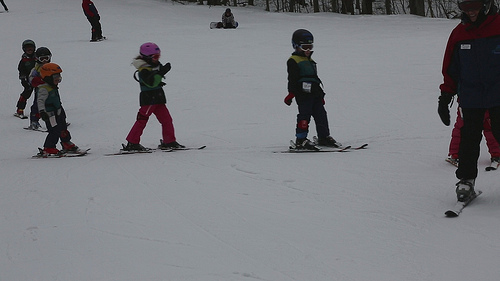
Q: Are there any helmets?
A: Yes, there is a helmet.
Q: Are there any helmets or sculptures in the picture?
A: Yes, there is a helmet.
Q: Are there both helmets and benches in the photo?
A: No, there is a helmet but no benches.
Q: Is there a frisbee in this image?
A: No, there are no frisbees.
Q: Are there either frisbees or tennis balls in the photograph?
A: No, there are no frisbees or tennis balls.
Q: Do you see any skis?
A: Yes, there are skis.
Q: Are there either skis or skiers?
A: Yes, there are skis.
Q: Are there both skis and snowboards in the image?
A: No, there are skis but no snowboards.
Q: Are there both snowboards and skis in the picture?
A: No, there are skis but no snowboards.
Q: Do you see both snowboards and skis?
A: No, there are skis but no snowboards.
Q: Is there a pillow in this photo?
A: No, there are no pillows.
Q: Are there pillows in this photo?
A: No, there are no pillows.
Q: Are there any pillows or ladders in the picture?
A: No, there are no pillows or ladders.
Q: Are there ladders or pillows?
A: No, there are no pillows or ladders.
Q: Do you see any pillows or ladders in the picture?
A: No, there are no pillows or ladders.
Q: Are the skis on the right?
A: Yes, the skis are on the right of the image.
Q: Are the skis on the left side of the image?
A: No, the skis are on the right of the image.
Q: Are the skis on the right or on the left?
A: The skis are on the right of the image.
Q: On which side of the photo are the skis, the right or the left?
A: The skis are on the right of the image.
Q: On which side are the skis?
A: The skis are on the right of the image.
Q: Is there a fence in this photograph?
A: No, there are no fences.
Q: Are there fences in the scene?
A: No, there are no fences.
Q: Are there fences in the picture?
A: No, there are no fences.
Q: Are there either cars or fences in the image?
A: No, there are no fences or cars.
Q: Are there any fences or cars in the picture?
A: No, there are no fences or cars.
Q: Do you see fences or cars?
A: No, there are no fences or cars.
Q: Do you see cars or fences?
A: No, there are no fences or cars.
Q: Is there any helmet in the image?
A: Yes, there is a helmet.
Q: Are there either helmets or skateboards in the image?
A: Yes, there is a helmet.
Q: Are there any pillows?
A: No, there are no pillows.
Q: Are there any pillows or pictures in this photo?
A: No, there are no pillows or pictures.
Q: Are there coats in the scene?
A: Yes, there is a coat.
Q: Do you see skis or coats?
A: Yes, there is a coat.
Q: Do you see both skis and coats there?
A: Yes, there are both a coat and skis.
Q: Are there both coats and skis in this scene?
A: Yes, there are both a coat and skis.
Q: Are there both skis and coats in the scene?
A: Yes, there are both a coat and skis.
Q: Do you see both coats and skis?
A: Yes, there are both a coat and skis.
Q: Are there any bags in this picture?
A: No, there are no bags.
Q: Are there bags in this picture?
A: No, there are no bags.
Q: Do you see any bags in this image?
A: No, there are no bags.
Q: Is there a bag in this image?
A: No, there are no bags.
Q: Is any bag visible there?
A: No, there are no bags.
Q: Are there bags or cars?
A: No, there are no bags or cars.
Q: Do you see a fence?
A: No, there are no fences.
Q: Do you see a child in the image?
A: Yes, there are children.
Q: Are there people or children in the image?
A: Yes, there are children.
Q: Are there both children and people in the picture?
A: Yes, there are both children and people.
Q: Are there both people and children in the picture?
A: Yes, there are both children and people.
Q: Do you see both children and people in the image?
A: Yes, there are both children and people.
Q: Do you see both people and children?
A: Yes, there are both children and people.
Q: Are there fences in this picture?
A: No, there are no fences.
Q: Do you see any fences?
A: No, there are no fences.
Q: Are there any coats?
A: Yes, there is a coat.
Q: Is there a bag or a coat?
A: Yes, there is a coat.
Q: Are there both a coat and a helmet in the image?
A: Yes, there are both a coat and a helmet.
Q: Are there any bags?
A: No, there are no bags.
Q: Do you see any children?
A: Yes, there are children.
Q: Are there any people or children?
A: Yes, there are children.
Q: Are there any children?
A: Yes, there are children.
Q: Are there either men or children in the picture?
A: Yes, there are children.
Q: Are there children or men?
A: Yes, there are children.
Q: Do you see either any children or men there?
A: Yes, there are children.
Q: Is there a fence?
A: No, there are no fences.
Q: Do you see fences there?
A: No, there are no fences.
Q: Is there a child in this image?
A: Yes, there are children.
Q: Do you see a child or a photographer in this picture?
A: Yes, there are children.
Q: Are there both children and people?
A: Yes, there are both children and a person.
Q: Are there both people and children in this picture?
A: Yes, there are both children and a person.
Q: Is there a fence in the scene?
A: No, there are no fences.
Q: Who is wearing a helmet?
A: The children are wearing a helmet.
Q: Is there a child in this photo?
A: Yes, there is a child.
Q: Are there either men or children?
A: Yes, there is a child.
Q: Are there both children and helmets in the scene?
A: Yes, there are both a child and a helmet.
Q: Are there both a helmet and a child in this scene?
A: Yes, there are both a child and a helmet.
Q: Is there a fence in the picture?
A: No, there are no fences.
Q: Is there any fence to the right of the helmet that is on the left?
A: No, there is a child to the right of the helmet.